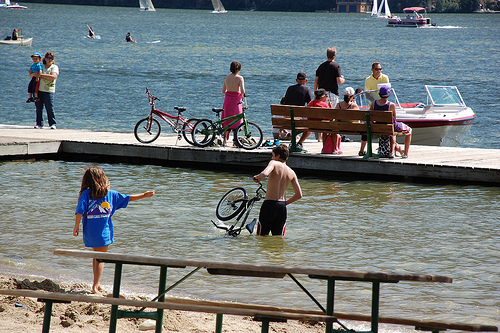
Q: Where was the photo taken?
A: At the lake.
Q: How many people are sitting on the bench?
A: 4.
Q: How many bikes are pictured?
A: Three.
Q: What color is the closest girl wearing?
A: Blue.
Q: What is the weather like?
A: Sunny.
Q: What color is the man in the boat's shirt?
A: Yellow.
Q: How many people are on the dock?
A: 8.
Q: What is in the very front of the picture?
A: Picnic table.